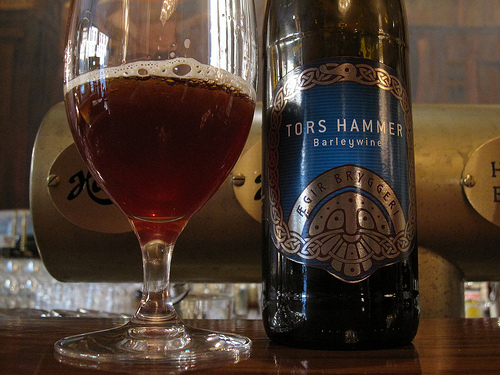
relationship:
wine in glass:
[61, 64, 261, 250] [66, 11, 243, 353]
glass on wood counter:
[52, 0, 257, 372] [0, 315, 498, 373]